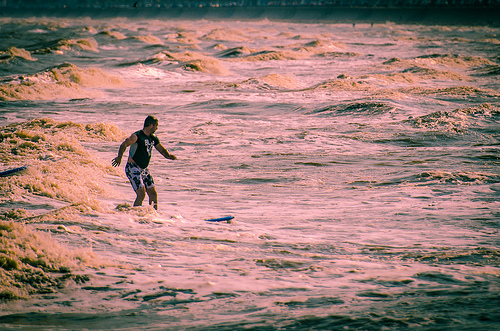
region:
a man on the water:
[104, 103, 182, 218]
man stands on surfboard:
[96, 108, 243, 240]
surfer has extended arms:
[105, 102, 183, 222]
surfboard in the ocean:
[175, 205, 235, 225]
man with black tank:
[105, 110, 180, 210]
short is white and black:
[120, 163, 162, 197]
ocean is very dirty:
[9, 14, 497, 317]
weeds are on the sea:
[7, 105, 109, 299]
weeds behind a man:
[6, 106, 242, 279]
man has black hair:
[122, 108, 171, 158]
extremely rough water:
[0, 14, 498, 319]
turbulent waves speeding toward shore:
[3, 42, 123, 312]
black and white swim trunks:
[120, 161, 159, 194]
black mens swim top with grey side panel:
[129, 130, 161, 166]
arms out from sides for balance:
[109, 137, 179, 168]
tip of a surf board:
[147, 210, 240, 232]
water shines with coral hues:
[0, 12, 477, 322]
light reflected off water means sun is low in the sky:
[8, 16, 491, 311]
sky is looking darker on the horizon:
[1, 0, 499, 32]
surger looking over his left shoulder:
[108, 95, 200, 221]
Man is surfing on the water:
[104, 112, 241, 229]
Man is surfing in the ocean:
[100, 108, 238, 230]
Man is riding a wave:
[105, 111, 236, 229]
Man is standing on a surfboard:
[196, 206, 235, 226]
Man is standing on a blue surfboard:
[199, 211, 235, 226]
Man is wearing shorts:
[117, 161, 157, 193]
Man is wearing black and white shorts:
[123, 161, 156, 193]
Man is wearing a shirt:
[129, 129, 156, 170]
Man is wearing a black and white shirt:
[125, 130, 162, 170]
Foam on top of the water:
[1, 10, 498, 320]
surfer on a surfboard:
[116, 111, 242, 233]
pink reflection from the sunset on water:
[227, 106, 329, 254]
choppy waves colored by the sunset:
[197, 34, 398, 164]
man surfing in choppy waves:
[55, 84, 238, 259]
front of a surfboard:
[196, 209, 246, 241]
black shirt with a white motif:
[127, 132, 161, 171]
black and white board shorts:
[123, 166, 160, 201]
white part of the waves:
[19, 135, 114, 260]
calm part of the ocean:
[225, 132, 357, 245]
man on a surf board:
[109, 93, 258, 278]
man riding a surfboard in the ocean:
[108, 112, 179, 212]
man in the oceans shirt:
[131, 127, 156, 168]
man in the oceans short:
[123, 161, 156, 191]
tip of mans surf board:
[205, 212, 237, 227]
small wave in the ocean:
[308, 69, 375, 96]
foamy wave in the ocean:
[1, 215, 101, 313]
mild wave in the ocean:
[2, 64, 122, 101]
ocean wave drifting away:
[418, 109, 485, 139]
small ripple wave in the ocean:
[404, 233, 499, 295]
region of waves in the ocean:
[51, 21, 274, 81]